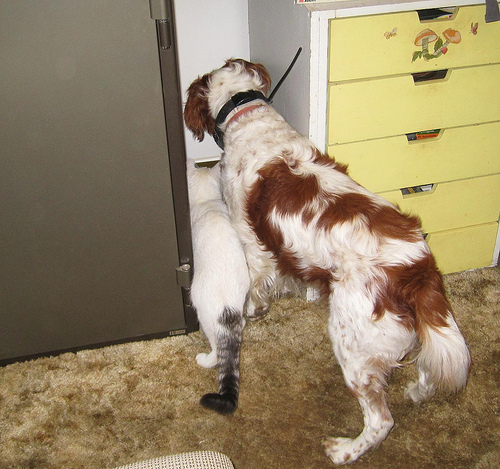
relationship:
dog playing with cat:
[183, 58, 470, 464] [186, 160, 256, 413]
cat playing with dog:
[186, 160, 256, 413] [183, 58, 470, 464]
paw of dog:
[320, 415, 391, 467] [183, 58, 470, 464]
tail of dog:
[407, 275, 474, 402] [183, 58, 470, 464]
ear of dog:
[183, 74, 210, 140] [183, 58, 470, 464]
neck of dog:
[216, 95, 275, 134] [183, 58, 470, 464]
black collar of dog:
[212, 90, 273, 146] [183, 58, 470, 464]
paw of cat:
[195, 350, 216, 368] [186, 160, 254, 414]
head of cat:
[187, 158, 220, 200] [139, 164, 269, 369]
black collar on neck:
[197, 84, 279, 141] [216, 95, 277, 135]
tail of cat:
[195, 308, 243, 413] [186, 160, 254, 414]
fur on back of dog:
[287, 163, 382, 248] [183, 58, 470, 464]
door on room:
[2, 7, 198, 367] [2, 2, 497, 455]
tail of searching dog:
[409, 275, 474, 397] [183, 58, 470, 464]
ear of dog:
[183, 74, 208, 144] [183, 58, 470, 464]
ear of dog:
[241, 55, 274, 85] [183, 58, 470, 464]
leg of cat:
[196, 316, 221, 366] [186, 160, 254, 414]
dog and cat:
[183, 58, 469, 468] [186, 160, 254, 414]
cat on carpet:
[186, 160, 254, 414] [27, 359, 179, 441]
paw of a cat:
[195, 350, 217, 368] [186, 160, 254, 414]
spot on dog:
[315, 187, 369, 222] [270, 145, 393, 336]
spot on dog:
[367, 200, 423, 240] [270, 145, 393, 336]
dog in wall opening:
[183, 58, 470, 464] [171, 9, 316, 299]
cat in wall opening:
[186, 160, 256, 413] [171, 9, 316, 299]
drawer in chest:
[320, 0, 496, 83] [245, 2, 497, 310]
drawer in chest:
[327, 60, 498, 142] [245, 2, 497, 310]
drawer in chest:
[328, 120, 498, 189] [245, 2, 497, 310]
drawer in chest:
[367, 172, 498, 236] [245, 2, 497, 310]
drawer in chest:
[429, 223, 498, 276] [245, 2, 497, 310]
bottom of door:
[150, 0, 198, 340] [2, 7, 198, 367]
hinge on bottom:
[152, 4, 174, 43] [150, 0, 198, 340]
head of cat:
[187, 158, 220, 202] [186, 160, 256, 413]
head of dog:
[188, 54, 270, 142] [199, 80, 304, 168]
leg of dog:
[318, 366, 395, 465] [147, 38, 466, 430]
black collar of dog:
[212, 90, 273, 146] [188, 69, 438, 325]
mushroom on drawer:
[405, 26, 466, 66] [320, 0, 496, 83]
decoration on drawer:
[403, 25, 465, 69] [320, 0, 496, 83]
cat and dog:
[186, 160, 254, 414] [118, 32, 495, 417]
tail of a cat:
[195, 308, 242, 414] [186, 160, 256, 413]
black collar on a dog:
[212, 90, 273, 146] [183, 58, 470, 464]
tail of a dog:
[407, 275, 474, 402] [122, 53, 440, 345]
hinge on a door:
[172, 260, 196, 290] [2, 7, 198, 367]